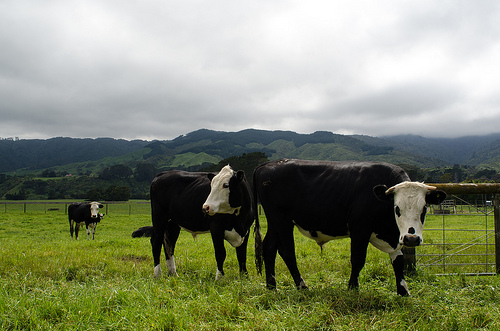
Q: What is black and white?
A: Cows.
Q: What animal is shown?
A: Cows.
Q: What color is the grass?
A: Green.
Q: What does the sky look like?
A: Cloudy and grey.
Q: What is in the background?
A: Mountains.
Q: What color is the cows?
A: Black and white.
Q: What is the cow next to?
A: Fence.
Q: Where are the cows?
A: Pasture.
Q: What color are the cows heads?
A: White.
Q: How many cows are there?
A: Four.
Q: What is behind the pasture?
A: Trees.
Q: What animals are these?
A: Cows.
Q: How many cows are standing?
A: Three.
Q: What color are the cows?
A: Black and white.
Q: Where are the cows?
A: In a pasture.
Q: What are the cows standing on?
A: Grass.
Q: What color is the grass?
A: Green.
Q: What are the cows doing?
A: Grazing.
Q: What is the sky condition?
A: Overcast.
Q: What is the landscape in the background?
A: Mountains.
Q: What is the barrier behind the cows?
A: Fence.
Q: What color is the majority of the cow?
A: Black.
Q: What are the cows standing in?
A: A field.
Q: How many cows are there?
A: Four.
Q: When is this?
A: Daytime.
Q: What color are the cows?
A: Black and white.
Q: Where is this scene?
A: A field.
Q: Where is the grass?
A: In the field.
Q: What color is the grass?
A: Green.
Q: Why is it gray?
A: It's overcast.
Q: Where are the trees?
A: On the mountain.